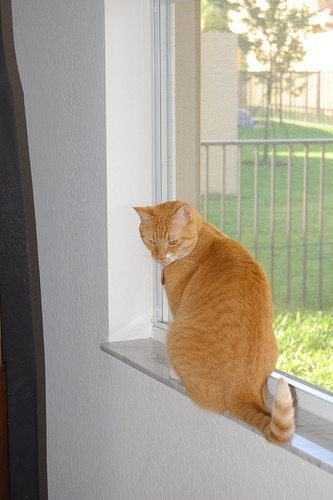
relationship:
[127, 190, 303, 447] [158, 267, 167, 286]
cat wearing collar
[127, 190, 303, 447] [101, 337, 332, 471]
cat on a window sill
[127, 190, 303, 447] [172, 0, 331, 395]
cat near a window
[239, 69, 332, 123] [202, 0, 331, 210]
fence in background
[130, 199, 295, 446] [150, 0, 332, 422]
cat sitting in window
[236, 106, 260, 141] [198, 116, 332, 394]
grill outside of yard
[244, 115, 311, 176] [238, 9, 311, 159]
stakes holding tree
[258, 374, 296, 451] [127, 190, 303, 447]
tail of cat